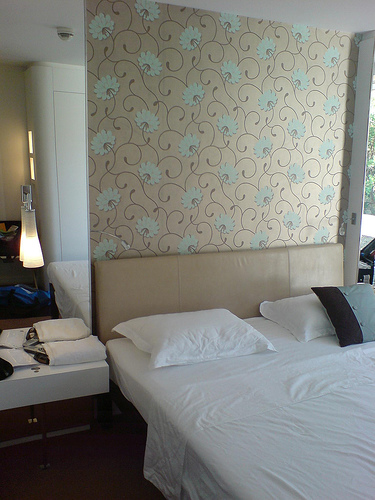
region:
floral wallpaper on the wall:
[87, 0, 357, 261]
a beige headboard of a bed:
[93, 241, 345, 341]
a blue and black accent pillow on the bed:
[310, 277, 373, 348]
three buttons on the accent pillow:
[341, 288, 367, 331]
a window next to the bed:
[362, 114, 373, 210]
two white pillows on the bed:
[111, 285, 337, 371]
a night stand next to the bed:
[0, 315, 111, 482]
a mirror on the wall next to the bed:
[0, 113, 91, 331]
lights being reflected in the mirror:
[16, 180, 44, 270]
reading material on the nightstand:
[0, 342, 41, 366]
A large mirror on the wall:
[1, 0, 93, 349]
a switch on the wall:
[349, 211, 359, 229]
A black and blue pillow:
[307, 282, 373, 346]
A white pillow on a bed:
[258, 291, 330, 344]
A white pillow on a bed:
[110, 303, 278, 368]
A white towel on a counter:
[42, 335, 106, 366]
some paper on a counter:
[1, 348, 34, 368]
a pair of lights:
[20, 203, 45, 269]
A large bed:
[109, 314, 373, 498]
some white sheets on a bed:
[142, 346, 373, 498]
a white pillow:
[113, 303, 280, 369]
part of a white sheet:
[139, 342, 373, 498]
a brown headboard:
[96, 239, 347, 342]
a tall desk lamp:
[16, 182, 47, 291]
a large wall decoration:
[86, 3, 350, 255]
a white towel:
[45, 333, 107, 365]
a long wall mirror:
[0, 0, 97, 321]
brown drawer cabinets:
[0, 397, 96, 474]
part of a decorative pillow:
[311, 285, 371, 346]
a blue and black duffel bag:
[1, 283, 52, 315]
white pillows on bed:
[116, 297, 353, 363]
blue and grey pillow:
[324, 292, 374, 364]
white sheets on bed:
[144, 320, 373, 467]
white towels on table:
[34, 324, 104, 362]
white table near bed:
[1, 358, 108, 401]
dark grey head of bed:
[119, 234, 332, 327]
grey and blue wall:
[108, 107, 314, 238]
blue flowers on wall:
[112, 101, 337, 235]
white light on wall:
[22, 207, 58, 272]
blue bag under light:
[7, 279, 76, 319]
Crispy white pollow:
[122, 307, 273, 358]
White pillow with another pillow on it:
[257, 278, 372, 350]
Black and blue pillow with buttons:
[308, 280, 373, 349]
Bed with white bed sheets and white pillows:
[104, 286, 374, 498]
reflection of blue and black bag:
[1, 282, 51, 317]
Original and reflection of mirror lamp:
[17, 185, 46, 269]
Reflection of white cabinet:
[20, 61, 90, 283]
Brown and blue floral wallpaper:
[83, 0, 348, 250]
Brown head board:
[87, 238, 347, 343]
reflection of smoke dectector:
[58, 28, 74, 43]